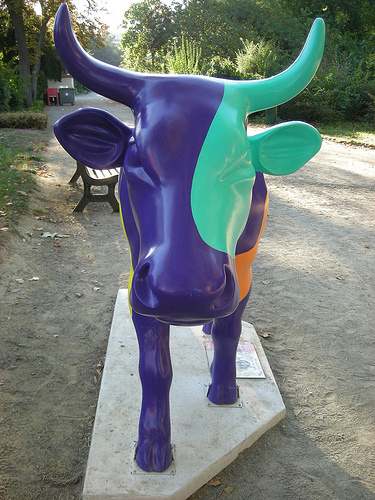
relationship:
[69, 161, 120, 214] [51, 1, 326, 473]
bench behind bull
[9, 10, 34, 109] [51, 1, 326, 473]
trunk behind bull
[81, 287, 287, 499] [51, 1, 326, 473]
foundation under bull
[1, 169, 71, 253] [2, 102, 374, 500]
leaves on top of sand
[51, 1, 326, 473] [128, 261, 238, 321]
bull has nose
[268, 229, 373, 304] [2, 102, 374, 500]
tracks over sand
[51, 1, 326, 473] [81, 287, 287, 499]
bull on top of foundation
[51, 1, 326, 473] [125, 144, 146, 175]
bull has eye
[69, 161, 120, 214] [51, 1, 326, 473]
bench near bull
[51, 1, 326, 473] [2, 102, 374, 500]
bull on top of sand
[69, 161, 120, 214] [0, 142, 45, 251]
bench in front of grass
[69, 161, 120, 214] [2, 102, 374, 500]
bench on top of sand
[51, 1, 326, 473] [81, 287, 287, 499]
bull standing on foundation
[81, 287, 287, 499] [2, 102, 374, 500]
foundation built on sand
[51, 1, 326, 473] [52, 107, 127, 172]
bull has right ear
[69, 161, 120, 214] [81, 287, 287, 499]
bench behind foundation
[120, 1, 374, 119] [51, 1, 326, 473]
trees behind bull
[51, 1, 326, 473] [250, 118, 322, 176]
bull has left ear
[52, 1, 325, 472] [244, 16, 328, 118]
bull has horn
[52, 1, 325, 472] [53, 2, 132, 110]
bull has right horn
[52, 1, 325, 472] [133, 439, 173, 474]
bull has hoof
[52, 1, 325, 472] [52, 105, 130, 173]
bull has ear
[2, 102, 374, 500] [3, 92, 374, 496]
sand covering ground